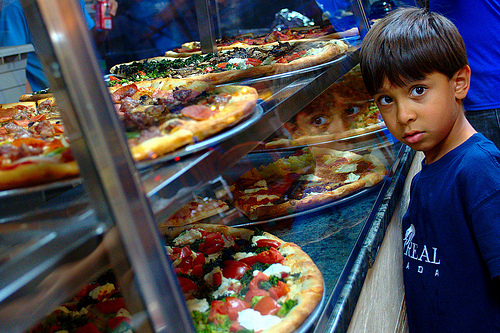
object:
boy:
[355, 6, 495, 330]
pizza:
[231, 150, 385, 210]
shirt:
[400, 132, 497, 331]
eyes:
[405, 85, 426, 98]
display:
[13, 2, 383, 321]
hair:
[355, 3, 472, 87]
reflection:
[271, 48, 379, 174]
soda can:
[95, 1, 116, 31]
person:
[0, 1, 113, 88]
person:
[423, 3, 499, 143]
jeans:
[467, 109, 499, 135]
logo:
[396, 223, 445, 281]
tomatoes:
[217, 258, 272, 311]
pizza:
[40, 229, 328, 332]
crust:
[362, 153, 385, 191]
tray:
[191, 150, 386, 228]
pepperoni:
[180, 99, 219, 127]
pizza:
[7, 80, 258, 191]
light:
[390, 12, 471, 40]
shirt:
[426, 0, 498, 105]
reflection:
[317, 1, 375, 50]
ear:
[450, 65, 470, 103]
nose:
[394, 102, 418, 127]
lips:
[401, 132, 430, 142]